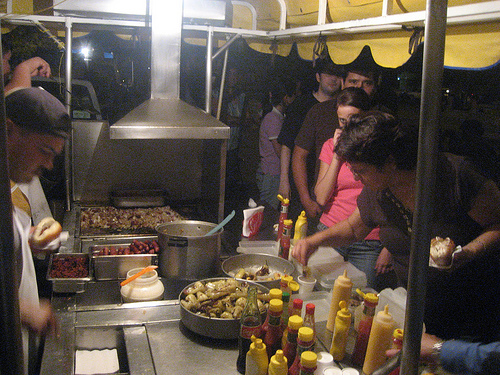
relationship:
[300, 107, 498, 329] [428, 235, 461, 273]
woman putting condiments on woman's hot dog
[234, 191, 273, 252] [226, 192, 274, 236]
napkins in holder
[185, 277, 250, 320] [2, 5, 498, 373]
yellow awning over stand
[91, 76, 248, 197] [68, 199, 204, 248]
fan hood over grill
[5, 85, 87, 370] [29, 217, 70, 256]
guy holding hot dog holding hot dog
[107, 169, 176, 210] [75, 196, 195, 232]
food on the grill on grill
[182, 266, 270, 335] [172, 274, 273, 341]
veggies in a pot in a pan full of potatoes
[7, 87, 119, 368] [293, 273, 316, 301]
guy dipping in a cup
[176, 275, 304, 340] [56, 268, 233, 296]
circular white bowl on stove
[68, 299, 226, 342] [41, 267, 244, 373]
line on silver on surface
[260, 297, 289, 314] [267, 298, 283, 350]
yellow lid on bottle